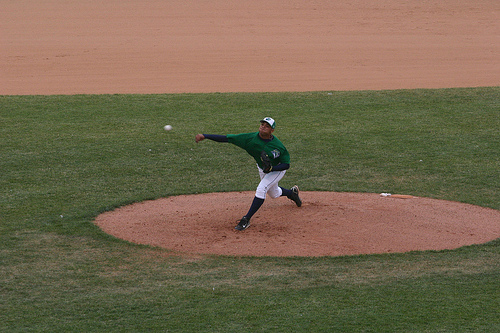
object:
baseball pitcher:
[198, 117, 305, 232]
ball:
[164, 124, 172, 130]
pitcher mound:
[99, 182, 500, 260]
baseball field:
[1, 0, 494, 330]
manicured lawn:
[1, 85, 498, 332]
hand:
[193, 133, 206, 143]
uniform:
[206, 128, 294, 220]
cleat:
[235, 219, 252, 230]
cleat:
[291, 183, 302, 207]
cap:
[260, 116, 276, 130]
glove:
[263, 166, 272, 174]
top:
[226, 131, 290, 172]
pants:
[253, 161, 284, 201]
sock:
[245, 196, 264, 220]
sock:
[279, 187, 292, 198]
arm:
[203, 133, 254, 144]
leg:
[245, 169, 285, 221]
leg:
[257, 162, 292, 200]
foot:
[236, 215, 252, 232]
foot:
[288, 184, 300, 206]